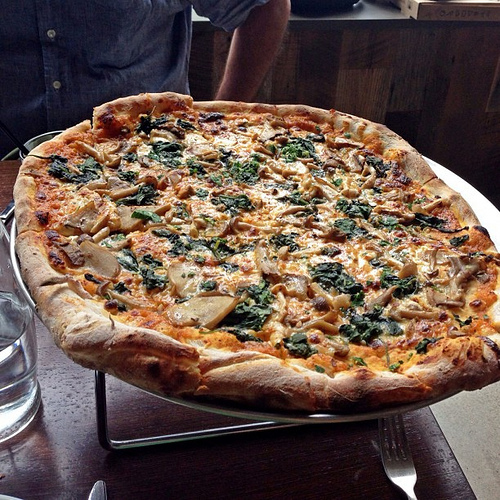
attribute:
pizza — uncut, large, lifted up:
[8, 82, 500, 422]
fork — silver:
[373, 410, 424, 500]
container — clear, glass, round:
[0, 223, 44, 453]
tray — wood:
[436, 152, 499, 235]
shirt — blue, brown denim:
[5, 1, 257, 91]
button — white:
[41, 23, 59, 44]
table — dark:
[6, 414, 467, 495]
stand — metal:
[89, 375, 296, 454]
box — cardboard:
[393, 1, 498, 24]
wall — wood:
[298, 30, 496, 129]